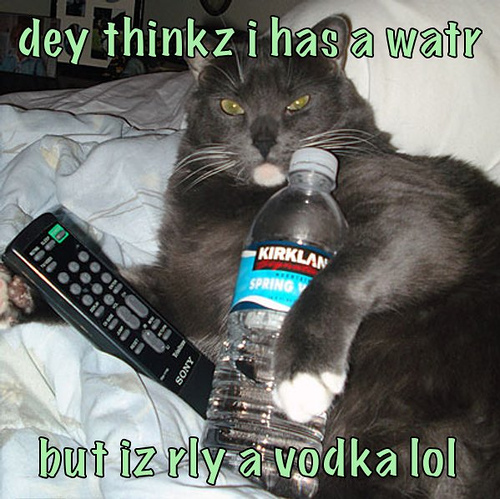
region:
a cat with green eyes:
[160, 45, 480, 463]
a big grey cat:
[181, 30, 480, 458]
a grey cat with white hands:
[182, 35, 486, 468]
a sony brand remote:
[16, 209, 213, 411]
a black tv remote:
[22, 188, 227, 425]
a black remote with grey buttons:
[22, 193, 229, 431]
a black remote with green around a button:
[27, 203, 224, 417]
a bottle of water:
[196, 141, 368, 496]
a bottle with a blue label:
[218, 143, 345, 463]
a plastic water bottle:
[214, 141, 348, 476]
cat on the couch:
[145, 18, 498, 497]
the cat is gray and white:
[148, 15, 498, 483]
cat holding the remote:
[6, 201, 210, 421]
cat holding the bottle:
[193, 138, 349, 498]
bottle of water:
[191, 119, 359, 493]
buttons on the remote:
[48, 253, 145, 330]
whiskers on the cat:
[177, 139, 236, 182]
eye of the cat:
[196, 85, 253, 120]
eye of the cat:
[269, 81, 315, 116]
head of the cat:
[165, 11, 392, 196]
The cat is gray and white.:
[11, 14, 490, 495]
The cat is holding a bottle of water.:
[1, 15, 498, 497]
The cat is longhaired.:
[1, 9, 498, 497]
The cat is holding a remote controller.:
[1, 9, 498, 497]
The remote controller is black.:
[1, 196, 226, 433]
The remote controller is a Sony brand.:
[1, 196, 231, 439]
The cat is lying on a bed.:
[0, 6, 499, 496]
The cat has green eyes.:
[1, 9, 498, 497]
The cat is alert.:
[1, 10, 499, 497]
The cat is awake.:
[0, 11, 498, 497]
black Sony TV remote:
[1, 211, 228, 413]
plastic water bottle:
[201, 139, 351, 495]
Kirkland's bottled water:
[195, 139, 345, 496]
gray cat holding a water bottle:
[1, 9, 498, 489]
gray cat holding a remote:
[0, 21, 495, 495]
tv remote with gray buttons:
[5, 198, 228, 432]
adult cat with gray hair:
[144, 15, 494, 493]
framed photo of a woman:
[0, 12, 64, 84]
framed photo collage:
[51, 2, 150, 76]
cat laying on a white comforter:
[5, 23, 497, 493]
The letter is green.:
[11, 9, 45, 69]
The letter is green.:
[29, 430, 63, 482]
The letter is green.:
[59, 433, 90, 483]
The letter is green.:
[87, 428, 113, 483]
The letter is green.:
[113, 425, 135, 485]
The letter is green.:
[130, 434, 161, 486]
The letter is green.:
[199, 433, 231, 496]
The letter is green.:
[235, 430, 268, 492]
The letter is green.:
[269, 419, 299, 496]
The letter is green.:
[345, 427, 375, 491]